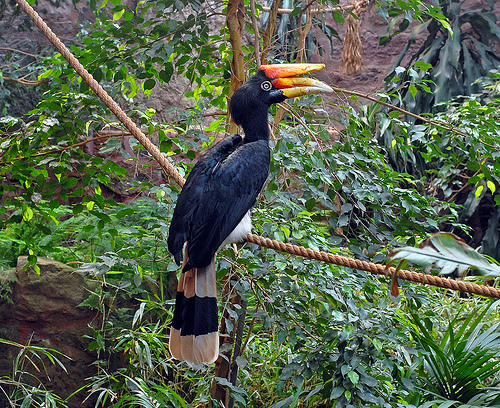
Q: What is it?
A: A bird.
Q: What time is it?
A: Daytime.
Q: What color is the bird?
A: Black.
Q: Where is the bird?
A: On a rope.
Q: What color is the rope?
A: Brown.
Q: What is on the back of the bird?
A: Feathers.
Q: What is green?
A: The leaves.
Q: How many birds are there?
A: One.